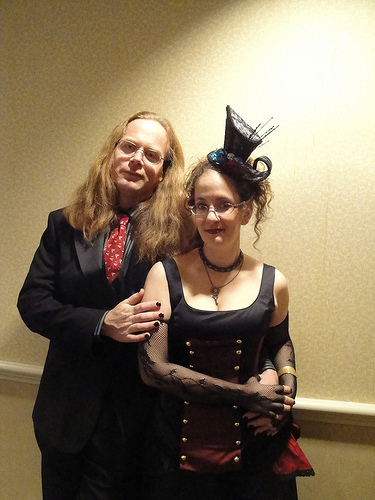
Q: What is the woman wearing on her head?
A: A hat.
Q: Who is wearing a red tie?
A: The man.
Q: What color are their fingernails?
A: Black.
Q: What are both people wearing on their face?
A: Glasses.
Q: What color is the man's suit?
A: Black.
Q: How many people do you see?
A: 2.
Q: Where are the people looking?
A: At the camera.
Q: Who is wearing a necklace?
A: The woman.